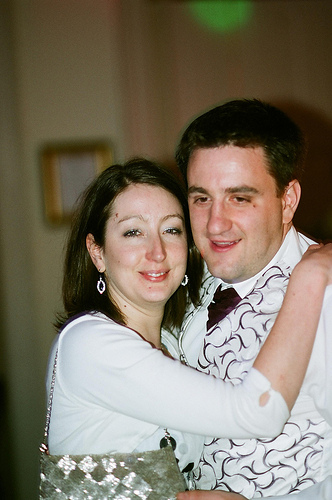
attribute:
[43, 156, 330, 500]
woman — smiling, lady, light skinned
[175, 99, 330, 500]
man — standing, here, laughing, smiling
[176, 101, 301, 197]
hair — brown, here, black, short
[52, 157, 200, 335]
hair — shoulder length, long, brown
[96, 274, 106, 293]
ear ring — hoop, here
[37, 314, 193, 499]
purse — sequined, silver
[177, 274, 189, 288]
ear ring — hoop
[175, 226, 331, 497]
vest — white, maroon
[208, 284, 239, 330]
tie — maroon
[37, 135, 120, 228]
mirror — gold framed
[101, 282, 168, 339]
neck — here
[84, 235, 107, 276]
ear — here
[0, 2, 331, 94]
background — blurry